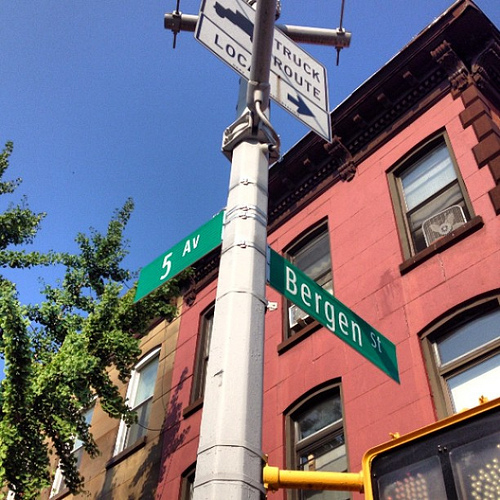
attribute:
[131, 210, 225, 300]
street sign — green, white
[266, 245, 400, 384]
street sign — green, white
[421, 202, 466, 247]
fan — large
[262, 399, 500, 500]
street light — electronic, yellow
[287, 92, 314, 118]
arrow — black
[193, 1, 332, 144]
sign — black, white, informational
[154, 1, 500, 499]
building — tall, pink, red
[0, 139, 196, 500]
tree — green, large, tall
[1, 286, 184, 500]
building — tan, tall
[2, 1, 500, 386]
sky — blue, clear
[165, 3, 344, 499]
pole — metal, tall